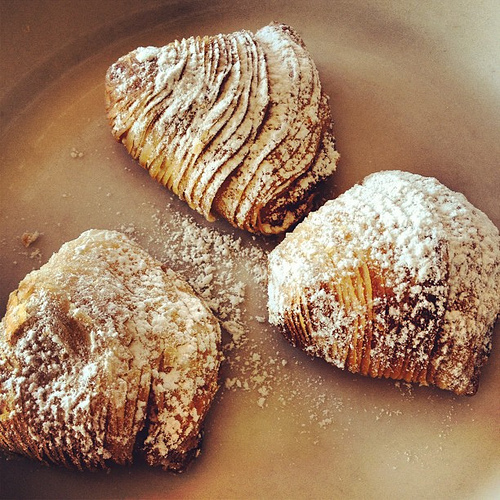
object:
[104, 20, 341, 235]
dessert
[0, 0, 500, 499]
plate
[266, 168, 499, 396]
dessert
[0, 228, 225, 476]
dessert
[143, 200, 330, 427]
powdered sugar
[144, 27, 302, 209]
sugar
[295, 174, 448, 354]
sugar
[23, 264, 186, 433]
powdered sugar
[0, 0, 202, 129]
shadow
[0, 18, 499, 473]
delicate